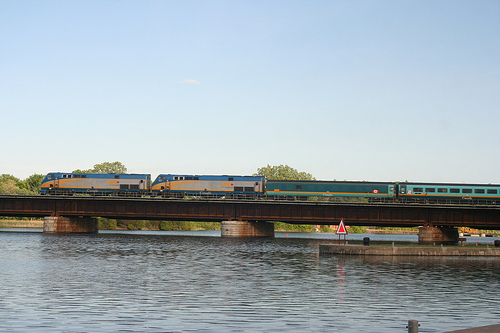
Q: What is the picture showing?
A: It is showing a lake.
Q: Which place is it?
A: It is a lake.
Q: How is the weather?
A: It is cloudless.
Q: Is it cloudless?
A: Yes, it is cloudless.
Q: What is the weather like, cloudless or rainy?
A: It is cloudless.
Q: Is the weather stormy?
A: No, it is cloudless.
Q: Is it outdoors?
A: Yes, it is outdoors.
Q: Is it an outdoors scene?
A: Yes, it is outdoors.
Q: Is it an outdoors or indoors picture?
A: It is outdoors.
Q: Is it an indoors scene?
A: No, it is outdoors.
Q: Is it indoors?
A: No, it is outdoors.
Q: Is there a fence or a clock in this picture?
A: No, there are no fences or clocks.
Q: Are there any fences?
A: No, there are no fences.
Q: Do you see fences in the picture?
A: No, there are no fences.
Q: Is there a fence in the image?
A: No, there are no fences.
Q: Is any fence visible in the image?
A: No, there are no fences.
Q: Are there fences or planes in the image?
A: No, there are no fences or planes.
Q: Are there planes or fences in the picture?
A: No, there are no fences or planes.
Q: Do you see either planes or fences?
A: No, there are no fences or planes.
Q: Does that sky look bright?
A: Yes, the sky is bright.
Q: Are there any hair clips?
A: No, there are no hair clips.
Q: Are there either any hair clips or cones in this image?
A: No, there are no hair clips or cones.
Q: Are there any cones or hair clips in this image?
A: No, there are no hair clips or cones.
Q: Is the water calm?
A: Yes, the water is calm.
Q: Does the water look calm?
A: Yes, the water is calm.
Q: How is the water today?
A: The water is calm.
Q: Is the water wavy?
A: No, the water is calm.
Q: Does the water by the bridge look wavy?
A: No, the water is calm.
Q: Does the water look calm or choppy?
A: The water is calm.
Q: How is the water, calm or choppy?
A: The water is calm.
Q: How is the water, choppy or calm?
A: The water is calm.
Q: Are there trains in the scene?
A: Yes, there is a train.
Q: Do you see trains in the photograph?
A: Yes, there is a train.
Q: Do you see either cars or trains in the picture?
A: Yes, there is a train.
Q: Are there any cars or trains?
A: Yes, there is a train.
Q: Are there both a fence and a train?
A: No, there is a train but no fences.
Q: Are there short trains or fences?
A: Yes, there is a short train.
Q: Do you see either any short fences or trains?
A: Yes, there is a short train.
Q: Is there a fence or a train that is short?
A: Yes, the train is short.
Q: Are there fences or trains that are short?
A: Yes, the train is short.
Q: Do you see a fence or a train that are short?
A: Yes, the train is short.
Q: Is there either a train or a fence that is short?
A: Yes, the train is short.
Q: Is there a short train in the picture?
A: Yes, there is a short train.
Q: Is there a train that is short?
A: Yes, there is a train that is short.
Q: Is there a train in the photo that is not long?
A: Yes, there is a short train.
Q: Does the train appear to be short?
A: Yes, the train is short.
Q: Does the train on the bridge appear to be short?
A: Yes, the train is short.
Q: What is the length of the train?
A: The train is short.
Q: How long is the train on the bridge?
A: The train is short.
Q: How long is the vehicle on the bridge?
A: The train is short.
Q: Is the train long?
A: No, the train is short.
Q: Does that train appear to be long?
A: No, the train is short.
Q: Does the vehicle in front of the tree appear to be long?
A: No, the train is short.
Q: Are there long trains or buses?
A: No, there is a train but it is short.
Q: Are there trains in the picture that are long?
A: No, there is a train but it is short.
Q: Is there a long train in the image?
A: No, there is a train but it is short.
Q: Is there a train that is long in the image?
A: No, there is a train but it is short.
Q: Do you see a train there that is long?
A: No, there is a train but it is short.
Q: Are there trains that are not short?
A: No, there is a train but it is short.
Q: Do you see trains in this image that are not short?
A: No, there is a train but it is short.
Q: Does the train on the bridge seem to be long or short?
A: The train is short.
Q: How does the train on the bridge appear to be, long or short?
A: The train is short.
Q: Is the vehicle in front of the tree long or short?
A: The train is short.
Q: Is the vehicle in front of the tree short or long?
A: The train is short.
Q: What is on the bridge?
A: The train is on the bridge.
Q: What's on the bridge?
A: The train is on the bridge.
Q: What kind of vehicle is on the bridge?
A: The vehicle is a train.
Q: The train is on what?
A: The train is on the bridge.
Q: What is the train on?
A: The train is on the bridge.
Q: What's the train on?
A: The train is on the bridge.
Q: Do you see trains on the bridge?
A: Yes, there is a train on the bridge.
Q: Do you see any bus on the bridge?
A: No, there is a train on the bridge.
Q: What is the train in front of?
A: The train is in front of the tree.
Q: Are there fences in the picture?
A: No, there are no fences.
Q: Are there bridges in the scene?
A: Yes, there is a bridge.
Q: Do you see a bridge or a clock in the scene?
A: Yes, there is a bridge.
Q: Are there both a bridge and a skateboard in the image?
A: No, there is a bridge but no skateboards.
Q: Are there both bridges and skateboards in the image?
A: No, there is a bridge but no skateboards.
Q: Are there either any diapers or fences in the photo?
A: No, there are no fences or diapers.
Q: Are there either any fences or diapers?
A: No, there are no fences or diapers.